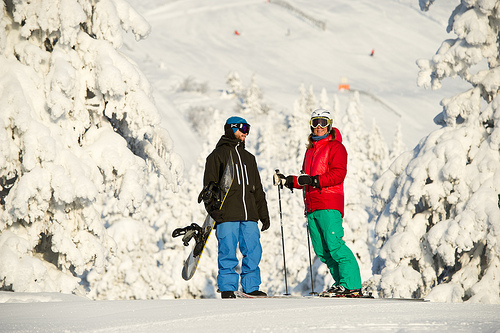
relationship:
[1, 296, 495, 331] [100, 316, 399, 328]
ground covered in snow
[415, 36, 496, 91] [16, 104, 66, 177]
leaves covered in snow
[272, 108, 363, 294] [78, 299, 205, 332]
man standing in snow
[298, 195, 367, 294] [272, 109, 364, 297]
pants on man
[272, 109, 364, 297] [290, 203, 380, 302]
man wearing pants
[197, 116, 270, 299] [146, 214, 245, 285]
guy holding snowboard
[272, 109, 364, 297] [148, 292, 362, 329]
man standing on snow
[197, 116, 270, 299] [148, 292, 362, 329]
guy standing on snow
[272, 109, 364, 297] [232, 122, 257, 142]
man wearing goggles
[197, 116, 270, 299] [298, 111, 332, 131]
guy wearing goggles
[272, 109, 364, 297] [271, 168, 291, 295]
man holding ski pole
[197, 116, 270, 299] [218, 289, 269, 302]
guy wearing boots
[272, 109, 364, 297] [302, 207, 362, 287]
man wearing pants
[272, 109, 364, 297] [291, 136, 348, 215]
man wearing coat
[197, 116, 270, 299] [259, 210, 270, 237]
guy wearing gloves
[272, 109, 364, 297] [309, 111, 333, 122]
man wearing hat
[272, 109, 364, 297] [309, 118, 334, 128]
man wearing goggles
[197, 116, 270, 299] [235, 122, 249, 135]
guy wearing goggles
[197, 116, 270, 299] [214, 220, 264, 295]
guy wearing pants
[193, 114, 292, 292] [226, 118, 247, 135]
guy wearing hat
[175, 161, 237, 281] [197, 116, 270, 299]
snowboard beside guy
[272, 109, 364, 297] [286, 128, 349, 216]
man wearing a coat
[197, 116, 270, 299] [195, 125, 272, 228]
guy wearing a coat